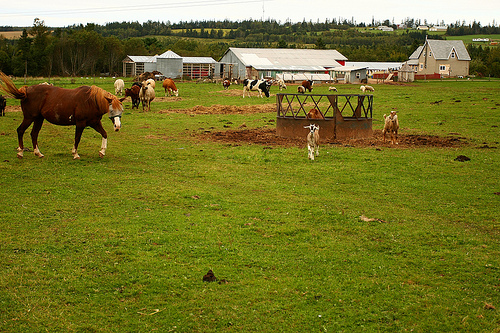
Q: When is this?
A: Daytime.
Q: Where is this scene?
A: A farm.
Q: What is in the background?
A: Trees.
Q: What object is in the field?
A: A feeding trough.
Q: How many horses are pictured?
A: One.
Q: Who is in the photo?
A: No one is in the photo.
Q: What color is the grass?
A: Green.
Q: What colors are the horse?
A: Brown and white.